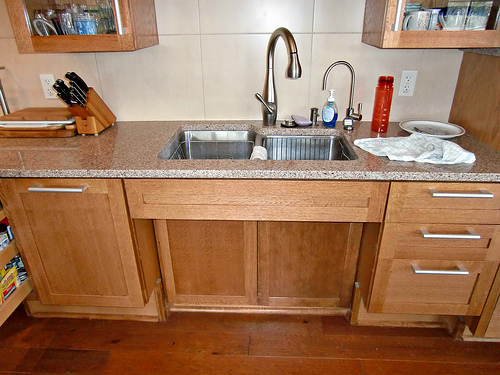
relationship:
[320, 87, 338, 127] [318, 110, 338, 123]
bottle filled with hand soap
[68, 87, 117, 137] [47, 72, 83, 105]
block of kitchen knives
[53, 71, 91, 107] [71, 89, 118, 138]
kitchen knives in block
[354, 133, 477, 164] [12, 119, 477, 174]
rag on counter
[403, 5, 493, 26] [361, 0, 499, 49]
cups in cabinet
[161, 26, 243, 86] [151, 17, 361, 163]
tile above sink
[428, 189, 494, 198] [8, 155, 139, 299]
handle on cabinet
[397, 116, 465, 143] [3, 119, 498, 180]
plate on counter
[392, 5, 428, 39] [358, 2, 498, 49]
mug in cabinet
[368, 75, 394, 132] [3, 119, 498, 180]
bottle on counter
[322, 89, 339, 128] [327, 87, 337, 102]
bottle with hand pump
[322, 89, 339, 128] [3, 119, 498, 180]
bottle on counter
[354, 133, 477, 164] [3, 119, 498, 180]
rag on counter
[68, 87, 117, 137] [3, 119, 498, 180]
block on counter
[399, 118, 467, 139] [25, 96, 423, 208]
plate on counter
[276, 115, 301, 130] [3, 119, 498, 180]
sink stopper on counter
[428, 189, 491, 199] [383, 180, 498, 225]
handle on drawer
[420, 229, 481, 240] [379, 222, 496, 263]
handle on drawer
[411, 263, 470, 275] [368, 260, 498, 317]
handle on drawer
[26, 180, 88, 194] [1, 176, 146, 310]
handle on cabinet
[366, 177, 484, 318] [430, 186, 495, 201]
drawer has handle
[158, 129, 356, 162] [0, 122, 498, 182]
sink in counter top